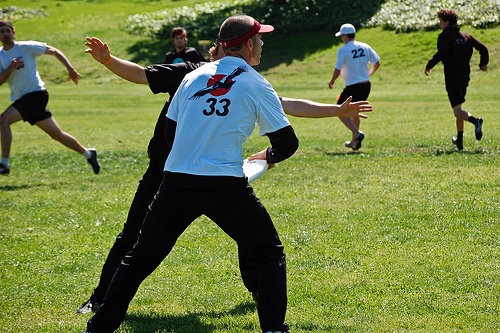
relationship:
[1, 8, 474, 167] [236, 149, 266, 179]
competitors in frisbee contest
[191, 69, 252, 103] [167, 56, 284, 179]
logo on shirt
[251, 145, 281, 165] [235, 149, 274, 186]
right hand holding frisbee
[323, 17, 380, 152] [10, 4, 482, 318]
person in field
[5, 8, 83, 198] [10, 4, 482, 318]
person in field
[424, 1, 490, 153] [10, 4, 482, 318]
person in field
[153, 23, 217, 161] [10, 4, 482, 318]
person in field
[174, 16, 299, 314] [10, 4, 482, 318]
person in field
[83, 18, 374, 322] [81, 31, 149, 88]
person has arm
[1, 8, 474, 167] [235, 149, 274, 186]
people playing frisbee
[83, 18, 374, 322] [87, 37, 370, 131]
man has arms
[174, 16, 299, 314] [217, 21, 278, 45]
man wearing visor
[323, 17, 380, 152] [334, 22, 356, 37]
man wearing ballcap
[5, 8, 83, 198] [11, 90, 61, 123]
man wearing shorts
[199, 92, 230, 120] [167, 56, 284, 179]
number 33 on shirt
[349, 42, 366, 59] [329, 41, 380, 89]
22 on shirt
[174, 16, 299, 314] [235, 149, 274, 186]
man holding frisbee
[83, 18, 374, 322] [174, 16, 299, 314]
player blocking man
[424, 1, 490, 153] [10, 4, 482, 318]
man playing on field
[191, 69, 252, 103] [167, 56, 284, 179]
eagle on shirt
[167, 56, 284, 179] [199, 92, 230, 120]
shirt has number 33